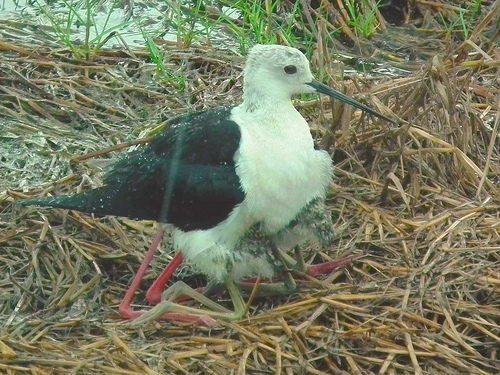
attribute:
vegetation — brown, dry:
[381, 151, 497, 368]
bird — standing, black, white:
[98, 47, 390, 320]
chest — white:
[231, 104, 307, 239]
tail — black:
[32, 172, 121, 243]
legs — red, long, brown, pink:
[133, 188, 342, 337]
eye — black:
[278, 51, 296, 87]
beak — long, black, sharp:
[285, 77, 408, 138]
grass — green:
[54, 2, 298, 61]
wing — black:
[7, 110, 228, 220]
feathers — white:
[246, 83, 333, 216]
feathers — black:
[149, 102, 250, 216]